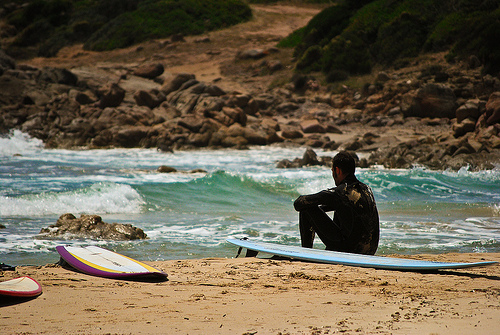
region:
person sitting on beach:
[291, 148, 385, 250]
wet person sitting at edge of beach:
[292, 144, 384, 258]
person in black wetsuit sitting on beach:
[289, 146, 383, 258]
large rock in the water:
[29, 209, 149, 240]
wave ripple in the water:
[204, 167, 278, 197]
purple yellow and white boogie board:
[54, 237, 167, 284]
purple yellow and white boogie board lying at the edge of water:
[55, 239, 167, 284]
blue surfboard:
[228, 232, 497, 273]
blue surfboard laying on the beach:
[226, 234, 494, 274]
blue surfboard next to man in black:
[226, 234, 491, 272]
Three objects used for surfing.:
[0, 235, 499, 303]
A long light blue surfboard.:
[225, 233, 499, 275]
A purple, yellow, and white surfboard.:
[54, 242, 169, 283]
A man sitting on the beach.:
[291, 148, 382, 259]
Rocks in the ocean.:
[33, 210, 154, 246]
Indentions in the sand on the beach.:
[167, 258, 496, 332]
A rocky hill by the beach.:
[0, 0, 497, 178]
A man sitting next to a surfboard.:
[225, 148, 497, 275]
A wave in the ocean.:
[0, 176, 160, 217]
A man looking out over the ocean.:
[291, 148, 381, 255]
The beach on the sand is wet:
[118, 298, 444, 332]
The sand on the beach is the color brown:
[64, 290, 457, 333]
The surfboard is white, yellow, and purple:
[52, 230, 179, 283]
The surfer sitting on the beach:
[238, 129, 470, 310]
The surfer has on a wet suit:
[291, 173, 387, 258]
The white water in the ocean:
[19, 185, 139, 217]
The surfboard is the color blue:
[226, 228, 498, 283]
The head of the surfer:
[326, 144, 364, 185]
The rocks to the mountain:
[51, 57, 252, 140]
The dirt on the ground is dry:
[86, 17, 277, 66]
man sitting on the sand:
[284, 143, 386, 257]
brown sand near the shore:
[0, 252, 499, 334]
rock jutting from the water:
[38, 205, 154, 243]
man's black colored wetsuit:
[293, 180, 383, 255]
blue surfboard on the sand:
[223, 229, 497, 279]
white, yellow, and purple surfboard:
[51, 238, 173, 286]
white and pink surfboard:
[1, 269, 46, 304]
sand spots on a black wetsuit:
[343, 185, 376, 255]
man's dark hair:
[332, 146, 359, 180]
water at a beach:
[1, 132, 498, 279]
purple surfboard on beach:
[50, 237, 175, 296]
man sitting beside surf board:
[226, 146, 496, 291]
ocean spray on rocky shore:
[4, 116, 59, 167]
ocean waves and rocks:
[125, 156, 250, 195]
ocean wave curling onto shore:
[3, 183, 153, 218]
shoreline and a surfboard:
[40, 238, 216, 290]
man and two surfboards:
[52, 141, 499, 300]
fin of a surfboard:
[223, 231, 273, 265]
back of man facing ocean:
[285, 142, 394, 261]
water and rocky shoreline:
[50, 98, 243, 178]